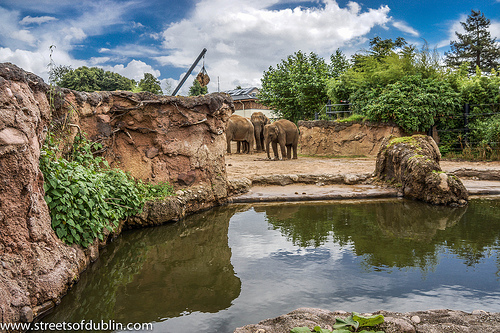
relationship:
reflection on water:
[66, 202, 244, 331] [26, 198, 497, 331]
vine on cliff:
[45, 132, 181, 249] [4, 75, 227, 313]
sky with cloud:
[3, 2, 497, 94] [156, 5, 398, 74]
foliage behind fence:
[258, 56, 494, 141] [291, 101, 411, 126]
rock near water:
[377, 131, 463, 203] [26, 198, 497, 331]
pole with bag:
[170, 47, 209, 97] [197, 68, 215, 88]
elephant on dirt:
[265, 120, 304, 158] [219, 152, 496, 208]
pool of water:
[35, 196, 489, 330] [26, 198, 497, 331]